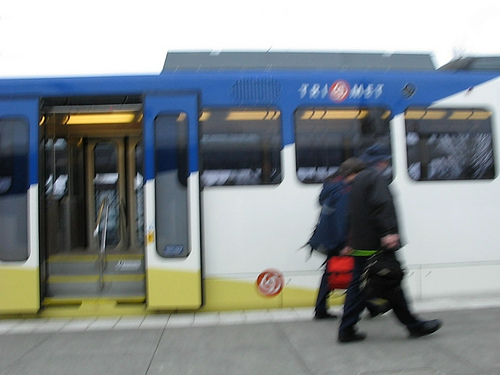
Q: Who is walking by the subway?
A: Two passengers.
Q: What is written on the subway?
A: Tri met.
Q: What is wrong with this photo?
A: It's blurry.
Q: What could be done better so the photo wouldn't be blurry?
A: Hold the camera still.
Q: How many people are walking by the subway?
A: Two.